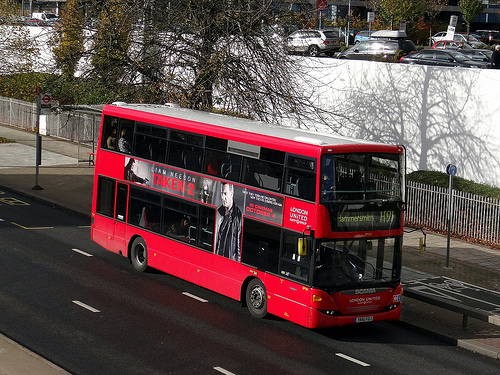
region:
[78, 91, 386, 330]
a double decker bus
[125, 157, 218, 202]
a banner advertising a movie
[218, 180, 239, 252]
a large image of Liam Neeson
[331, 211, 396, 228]
an advertisement for Monster energy drink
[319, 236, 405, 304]
the lower front windshield of a double decker bus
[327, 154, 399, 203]
the upper front windshield of a double decker bus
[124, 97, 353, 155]
the white top of a double decker bus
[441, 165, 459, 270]
a street sign in front of a bus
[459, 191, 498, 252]
a metal fence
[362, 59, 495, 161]
the shadow of a large tree on a white wall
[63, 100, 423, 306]
double decker bus on street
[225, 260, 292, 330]
black tire of the bus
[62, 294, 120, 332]
white line on the road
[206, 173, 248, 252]
picture on the bus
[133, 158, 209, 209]
Red and white words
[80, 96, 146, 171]
people on the bus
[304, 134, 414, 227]
front window of bus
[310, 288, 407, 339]
lights on the bus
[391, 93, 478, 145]
tree next to the bus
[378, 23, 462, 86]
cars in the background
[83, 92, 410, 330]
red double decker bus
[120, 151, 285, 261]
movie ad on bus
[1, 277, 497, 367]
three lane road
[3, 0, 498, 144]
trees along the road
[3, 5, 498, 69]
parking lot in background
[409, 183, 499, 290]
fence along the sidewalk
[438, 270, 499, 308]
bicycle lane on sidewalk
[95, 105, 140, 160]
people on the bus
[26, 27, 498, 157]
white parking lot wall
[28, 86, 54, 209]
street sign along road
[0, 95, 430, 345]
a red two level bus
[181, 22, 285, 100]
a tree with no leaves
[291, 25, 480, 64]
several cars parked in a parking lot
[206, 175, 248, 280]
a picture of a man on a bus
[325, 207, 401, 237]
digital letters and numbers on a bus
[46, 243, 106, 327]
white lines painted on a roadway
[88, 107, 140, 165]
people sitting on a bus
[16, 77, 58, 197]
a street sign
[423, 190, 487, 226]
a iron fence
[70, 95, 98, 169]
a bus stop shelter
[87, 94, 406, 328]
red double decker bus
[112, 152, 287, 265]
ad on the double decker bus advertising the movie Taken 2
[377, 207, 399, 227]
Bus number on the front right of the bus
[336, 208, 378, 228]
destination of the bus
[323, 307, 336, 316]
left side headlights of the bus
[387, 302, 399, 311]
right side head lights of the bus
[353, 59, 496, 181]
large shadow on the white wall of the tree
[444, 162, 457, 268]
blue bus stop sign on the edge of sidewalk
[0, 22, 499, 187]
long white wall on right side of the trees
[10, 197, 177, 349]
road that the double decker bus in traveling on